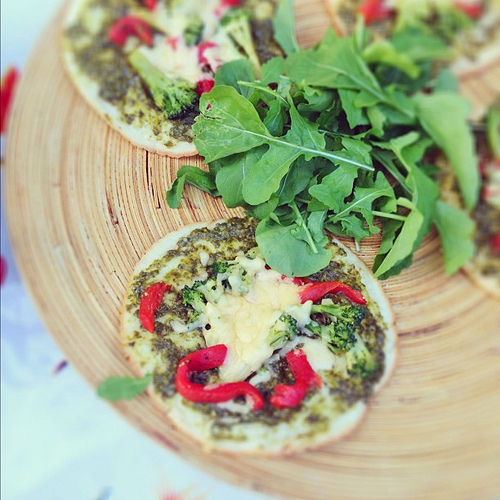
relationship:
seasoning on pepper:
[185, 217, 254, 244] [174, 345, 261, 407]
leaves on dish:
[191, 81, 375, 203] [0, 0, 499, 498]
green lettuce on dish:
[280, 42, 414, 120] [0, 0, 499, 498]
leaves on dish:
[251, 214, 328, 278] [0, 0, 499, 498]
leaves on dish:
[165, 162, 219, 208] [0, 0, 499, 498]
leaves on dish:
[321, 171, 396, 231] [0, 0, 499, 498]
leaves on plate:
[165, 162, 219, 208] [7, 102, 122, 296]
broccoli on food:
[127, 49, 198, 116] [65, 13, 287, 153]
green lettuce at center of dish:
[280, 42, 414, 120] [5, 2, 496, 495]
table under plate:
[7, 271, 118, 476] [374, 260, 497, 495]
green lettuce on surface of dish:
[165, 0, 497, 278] [0, 0, 499, 498]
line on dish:
[45, 122, 112, 244] [0, 0, 499, 498]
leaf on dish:
[96, 371, 150, 398] [5, 2, 496, 495]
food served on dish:
[56, 0, 499, 458] [0, 0, 499, 498]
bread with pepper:
[124, 217, 398, 454] [299, 274, 363, 304]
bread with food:
[124, 217, 398, 454] [135, 280, 166, 333]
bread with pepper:
[124, 217, 398, 454] [271, 349, 316, 411]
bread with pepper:
[124, 217, 398, 454] [174, 345, 261, 407]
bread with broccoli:
[124, 217, 398, 454] [317, 301, 367, 347]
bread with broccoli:
[124, 217, 398, 454] [342, 347, 384, 399]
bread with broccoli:
[124, 217, 398, 454] [182, 281, 204, 311]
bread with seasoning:
[124, 217, 398, 454] [127, 217, 388, 442]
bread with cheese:
[124, 217, 398, 454] [194, 257, 322, 377]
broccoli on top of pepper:
[272, 302, 362, 346] [270, 348, 322, 411]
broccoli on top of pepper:
[177, 255, 251, 317] [270, 348, 322, 411]